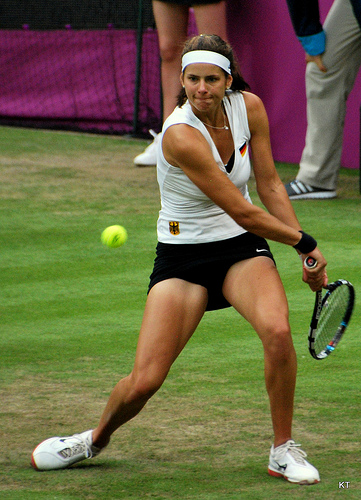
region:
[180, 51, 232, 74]
white headband on a woman's head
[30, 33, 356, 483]
woman swinging a tennis racket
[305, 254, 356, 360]
tennis racket in player's hands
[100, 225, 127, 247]
tennis ball flying in the air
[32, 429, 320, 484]
white tennis shoes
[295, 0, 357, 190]
leg of khaki pants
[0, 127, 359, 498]
grass growing on the ground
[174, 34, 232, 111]
tennis player's head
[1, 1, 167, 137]
black net behind the player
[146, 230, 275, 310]
tennis player's black shorts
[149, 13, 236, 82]
woman has dark hair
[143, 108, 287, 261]
woman has white shirt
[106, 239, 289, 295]
woman has black shorts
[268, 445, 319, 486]
woman has white shoes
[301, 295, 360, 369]
woman has black racket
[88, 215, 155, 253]
tennis ball near woman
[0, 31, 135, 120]
purple fence behind woman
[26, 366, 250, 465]
brown and dead grass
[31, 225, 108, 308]
green grass on court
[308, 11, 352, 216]
linesperson has grey pants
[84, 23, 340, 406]
a woman wearing white and black playing tennis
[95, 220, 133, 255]
a tennis ball in the air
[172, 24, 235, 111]
the head of a woman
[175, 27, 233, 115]
a woman wearing a white head band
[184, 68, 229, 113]
the face of a woman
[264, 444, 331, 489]
a white tennis shoe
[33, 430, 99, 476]
a white tennis shoe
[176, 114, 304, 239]
the arms of a woman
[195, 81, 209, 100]
the nose of a woman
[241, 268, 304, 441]
the leg of a woman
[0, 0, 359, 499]
The woman playing tennis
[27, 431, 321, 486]
White and red soled snickers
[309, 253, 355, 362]
A multi-colored tennis racket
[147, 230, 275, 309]
The dark playing shorts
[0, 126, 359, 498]
A leveled green tennis court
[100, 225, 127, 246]
The yellow tennis ball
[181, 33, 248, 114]
Player wearing a white head band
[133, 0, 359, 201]
Two persons standing in the background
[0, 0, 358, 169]
The purple covers in the background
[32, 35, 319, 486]
The skilled tennis sportswoman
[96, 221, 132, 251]
bright green tennis ball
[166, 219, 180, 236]
orange and black logo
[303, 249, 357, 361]
black tennis racquet being swung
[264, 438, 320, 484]
white and red tennis shoes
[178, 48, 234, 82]
white head band on head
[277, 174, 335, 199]
gray and white tennis shoes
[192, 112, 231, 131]
necklace around player neck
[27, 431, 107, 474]
red and white tennis shoe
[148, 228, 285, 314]
black tennis skort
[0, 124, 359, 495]
green grass as tennis court